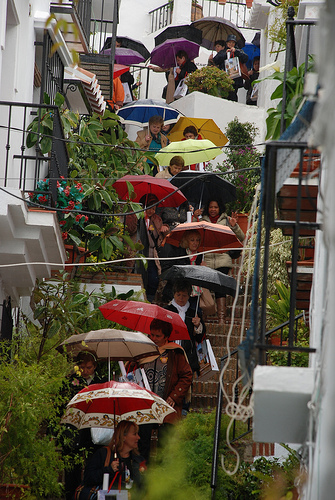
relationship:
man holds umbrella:
[174, 49, 198, 90] [148, 36, 202, 68]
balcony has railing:
[52, 0, 129, 102] [145, 1, 179, 29]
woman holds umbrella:
[125, 114, 174, 163] [114, 94, 184, 125]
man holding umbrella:
[170, 51, 196, 87] [144, 36, 205, 66]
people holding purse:
[83, 418, 140, 498] [78, 447, 132, 496]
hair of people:
[108, 419, 140, 457] [83, 418, 140, 498]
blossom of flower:
[75, 213, 89, 221] [76, 181, 85, 192]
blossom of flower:
[75, 180, 85, 193] [68, 199, 75, 208]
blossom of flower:
[37, 193, 47, 202] [76, 212, 90, 222]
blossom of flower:
[27, 190, 35, 196] [38, 194, 47, 201]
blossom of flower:
[60, 217, 66, 226] [61, 229, 69, 241]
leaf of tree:
[50, 451, 58, 458] [13, 328, 68, 489]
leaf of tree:
[36, 379, 48, 386] [13, 328, 68, 489]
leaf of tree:
[97, 237, 114, 259] [13, 328, 68, 489]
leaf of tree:
[48, 306, 61, 315] [13, 328, 68, 489]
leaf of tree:
[26, 339, 35, 346] [13, 328, 68, 489]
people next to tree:
[83, 418, 140, 498] [13, 328, 68, 489]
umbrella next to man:
[115, 96, 183, 123] [103, 76, 123, 105]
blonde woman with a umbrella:
[135, 115, 168, 152] [116, 97, 181, 127]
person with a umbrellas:
[116, 317, 193, 465] [103, 291, 186, 333]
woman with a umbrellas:
[76, 419, 143, 498] [66, 380, 167, 423]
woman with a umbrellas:
[141, 108, 174, 149] [110, 94, 215, 126]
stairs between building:
[192, 254, 262, 409] [246, 1, 334, 498]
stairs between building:
[192, 254, 262, 409] [0, 1, 121, 347]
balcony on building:
[47, 3, 121, 103] [0, 0, 120, 365]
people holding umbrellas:
[69, 27, 260, 498] [54, 15, 260, 431]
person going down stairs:
[145, 56, 179, 107] [70, 221, 250, 409]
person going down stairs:
[171, 47, 200, 88] [70, 221, 250, 409]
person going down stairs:
[132, 113, 170, 163] [70, 221, 250, 409]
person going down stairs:
[164, 277, 208, 375] [70, 221, 250, 409]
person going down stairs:
[191, 196, 243, 239] [70, 221, 250, 409]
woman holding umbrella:
[125, 316, 188, 462] [95, 294, 196, 344]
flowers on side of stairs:
[26, 176, 89, 241] [72, 175, 262, 409]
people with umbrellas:
[134, 168, 220, 340] [148, 155, 204, 321]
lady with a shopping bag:
[168, 274, 203, 407] [194, 336, 218, 387]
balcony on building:
[0, 99, 71, 211] [0, 1, 121, 347]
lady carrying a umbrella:
[163, 280, 217, 410] [96, 154, 203, 211]